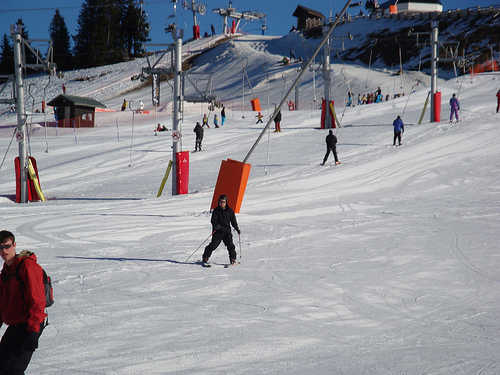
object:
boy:
[0, 229, 47, 375]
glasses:
[0, 242, 14, 250]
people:
[194, 122, 205, 152]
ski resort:
[0, 11, 500, 373]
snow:
[90, 263, 497, 372]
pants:
[221, 115, 226, 125]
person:
[393, 116, 405, 145]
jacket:
[393, 119, 405, 131]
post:
[170, 27, 183, 194]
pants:
[0, 323, 44, 375]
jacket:
[0, 250, 48, 339]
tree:
[120, 3, 150, 55]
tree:
[76, 5, 118, 58]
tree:
[43, 7, 72, 70]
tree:
[11, 18, 40, 70]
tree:
[0, 33, 17, 75]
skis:
[200, 261, 242, 268]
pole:
[321, 25, 331, 130]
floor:
[1, 139, 498, 375]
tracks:
[16, 212, 185, 254]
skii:
[319, 129, 341, 165]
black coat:
[211, 204, 240, 238]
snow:
[266, 192, 404, 285]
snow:
[326, 197, 431, 296]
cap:
[219, 195, 227, 200]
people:
[274, 108, 282, 132]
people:
[323, 130, 339, 166]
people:
[204, 195, 242, 264]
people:
[450, 93, 460, 123]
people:
[255, 111, 264, 124]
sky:
[1, 0, 500, 79]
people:
[348, 87, 405, 107]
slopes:
[1, 30, 500, 268]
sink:
[199, 227, 241, 268]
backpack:
[42, 268, 54, 307]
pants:
[202, 227, 236, 259]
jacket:
[326, 134, 338, 148]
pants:
[275, 121, 281, 131]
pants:
[195, 137, 203, 149]